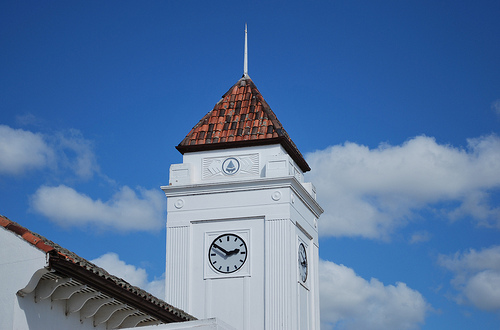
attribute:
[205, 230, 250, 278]
clock — large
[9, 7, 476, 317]
sky — cloudy, blue, clear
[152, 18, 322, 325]
tower — white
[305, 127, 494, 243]
cloud — white, fluffy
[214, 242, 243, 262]
hands — black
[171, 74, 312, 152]
roof — shingled, small, tiled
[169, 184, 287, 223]
trim — decorative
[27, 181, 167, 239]
cloud — white, fluffy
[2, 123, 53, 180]
cloud — white, fluffy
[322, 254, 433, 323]
cloud — white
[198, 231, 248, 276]
clock — white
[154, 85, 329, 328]
tower — large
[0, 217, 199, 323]
roof — medium sized, tiled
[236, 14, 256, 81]
antenna — small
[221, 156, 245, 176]
design — artistic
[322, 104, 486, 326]
clouds — scattered, white